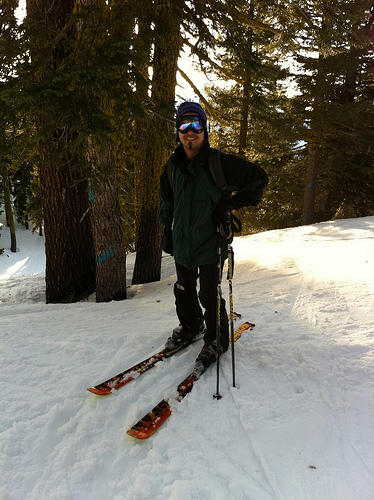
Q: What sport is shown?
A: Skiing.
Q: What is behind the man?
A: Trees.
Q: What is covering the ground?
A: Snow.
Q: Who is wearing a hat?
A: The man.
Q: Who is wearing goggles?
A: A man.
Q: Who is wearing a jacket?
A: The man.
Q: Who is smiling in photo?
A: A man.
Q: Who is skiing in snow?
A: A man.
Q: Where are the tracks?
A: Snow.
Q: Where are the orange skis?
A: Man's feet.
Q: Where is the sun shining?
A: Snow.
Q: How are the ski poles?
A: Upright.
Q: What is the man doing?
A: Skiing.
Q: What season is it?
A: Winter.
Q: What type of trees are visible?
A: Evergreen.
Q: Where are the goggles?
A: On the man's face.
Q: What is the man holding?
A: Ski poles.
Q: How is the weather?
A: Cold and clear.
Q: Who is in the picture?
A: Skier.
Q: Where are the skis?
A: On the man's feet.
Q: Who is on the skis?
A: Man in goggles.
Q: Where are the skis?
A: Snow.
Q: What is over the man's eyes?
A: Goggles.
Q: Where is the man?
A: Outside by a tree.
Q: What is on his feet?
A: Snow skis.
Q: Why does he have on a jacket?
A: It is cold.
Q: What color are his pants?
A: Black.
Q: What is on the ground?
A: Snow.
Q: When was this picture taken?
A: Daytime.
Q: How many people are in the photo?
A: One.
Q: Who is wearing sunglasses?
A: The man.